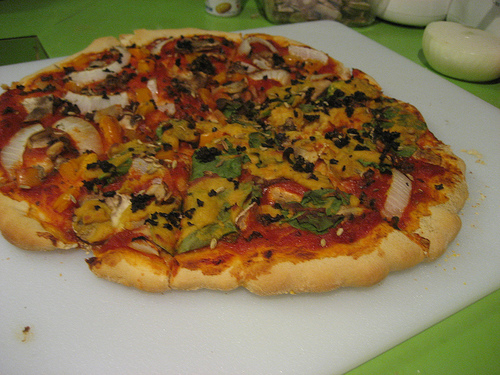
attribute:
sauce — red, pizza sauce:
[223, 221, 383, 246]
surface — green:
[392, 306, 498, 371]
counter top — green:
[339, 287, 499, 372]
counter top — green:
[3, 0, 275, 64]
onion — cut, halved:
[423, 20, 488, 77]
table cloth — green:
[0, 0, 500, 373]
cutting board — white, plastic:
[0, 20, 500, 374]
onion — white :
[420, 17, 498, 79]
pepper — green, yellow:
[174, 202, 238, 249]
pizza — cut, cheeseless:
[5, 20, 465, 292]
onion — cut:
[419, 19, 499, 83]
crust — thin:
[0, 156, 467, 298]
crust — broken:
[0, 195, 170, 293]